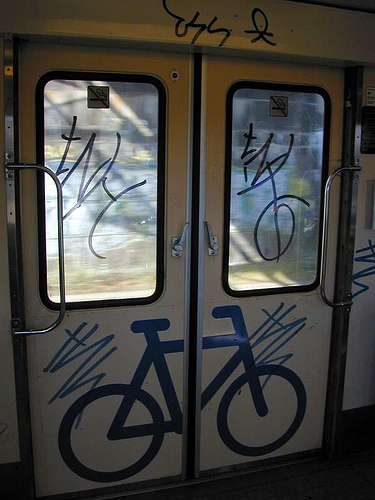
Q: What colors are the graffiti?
A: Blue and black.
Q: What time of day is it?
A: Daytime.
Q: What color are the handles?
A: Silver.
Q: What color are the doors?
A: White.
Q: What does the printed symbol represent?
A: A bicycle.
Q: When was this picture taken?
A: Daytime.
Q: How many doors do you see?
A: Two.